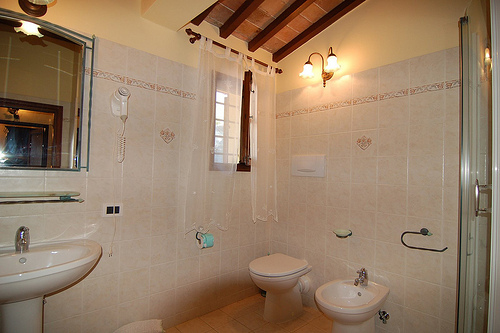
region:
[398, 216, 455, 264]
Curved metal towel holder on wall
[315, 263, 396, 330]
White porcelain bidet in bathroom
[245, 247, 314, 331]
White porcelain toilet in bathroom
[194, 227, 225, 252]
Toilet paper holder on wall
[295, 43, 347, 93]
Two bulb light fixture on wall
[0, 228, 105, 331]
White porcelain bathroom sink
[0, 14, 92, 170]
Shiny bathroom mirror on wall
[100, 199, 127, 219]
Electrical outlet on bathroom wall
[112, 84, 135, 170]
White hair dryer hanging on bathroom wall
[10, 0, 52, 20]
Underside of wall light fixture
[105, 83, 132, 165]
a white blowdryer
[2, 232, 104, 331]
a white pedestal sink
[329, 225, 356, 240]
a white soap dish holder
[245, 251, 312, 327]
a white toilet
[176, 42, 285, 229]
a window with white curtains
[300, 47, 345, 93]
a light fixture on the wall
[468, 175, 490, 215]
a shower door handle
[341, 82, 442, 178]
tile on the wall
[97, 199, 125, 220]
a wall outlet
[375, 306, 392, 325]
a water valve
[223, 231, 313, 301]
toilet seat is closed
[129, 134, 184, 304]
the wall is tiled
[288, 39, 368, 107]
the lights are on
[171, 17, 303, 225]
the curtains are translucent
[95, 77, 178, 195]
the blow dryer on the wall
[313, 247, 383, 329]
the bidet is white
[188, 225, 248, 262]
the toilet paper is green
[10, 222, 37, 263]
the faucet is off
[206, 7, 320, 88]
the ceiling is brown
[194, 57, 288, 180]
window pane is made of wood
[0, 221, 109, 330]
Sink in a bathroom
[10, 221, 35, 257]
Faucet is silver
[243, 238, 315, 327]
Toilet is cover with lid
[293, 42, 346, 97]
Lights are turn on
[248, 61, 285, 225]
White curtain of bathroom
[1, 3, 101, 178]
Mirror over the sink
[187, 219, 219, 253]
Paper toilet close to toilet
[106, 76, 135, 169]
Hair dryer on wall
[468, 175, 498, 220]
Handle of door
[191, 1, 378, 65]
Roof is made of wood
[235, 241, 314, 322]
a white toilet with the lid closed in the bathroom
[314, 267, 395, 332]
a white bidet with a silver faucet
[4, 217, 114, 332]
a white pedestal sink with a silver faucet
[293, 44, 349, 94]
A light fixture high up on the wall with two lamps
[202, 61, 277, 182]
a small window covered with lace curtains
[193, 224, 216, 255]
a toilet paper dispenser on the wall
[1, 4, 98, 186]
a mirror above the pedestal sink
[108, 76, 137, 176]
a white hair dryer attached to the wall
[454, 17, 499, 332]
a shower stall with a glass door and silver handle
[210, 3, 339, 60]
exposed wood beams in the ceiling of the bathroom